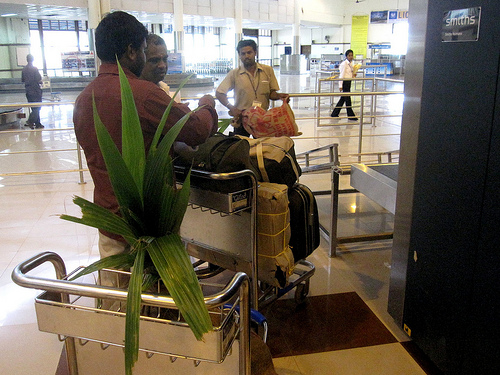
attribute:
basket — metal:
[94, 253, 171, 290]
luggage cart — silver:
[12, 248, 257, 373]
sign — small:
[439, 8, 480, 43]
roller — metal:
[150, 147, 335, 323]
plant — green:
[79, 120, 211, 339]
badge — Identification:
[246, 94, 266, 116]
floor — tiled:
[18, 177, 68, 242]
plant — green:
[50, 72, 218, 373]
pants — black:
[332, 78, 359, 120]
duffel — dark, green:
[165, 127, 256, 202]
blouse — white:
[331, 61, 356, 84]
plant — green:
[58, 53, 219, 373]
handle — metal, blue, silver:
[220, 302, 275, 342]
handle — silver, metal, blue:
[10, 248, 250, 307]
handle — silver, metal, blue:
[171, 162, 251, 191]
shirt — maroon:
[72, 65, 217, 213]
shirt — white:
[335, 58, 361, 88]